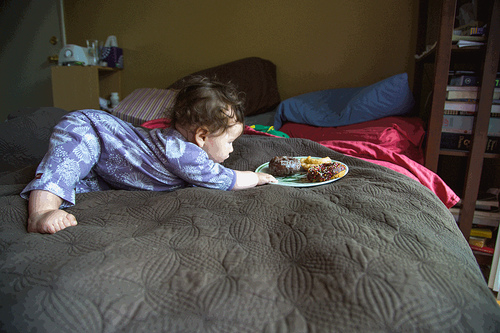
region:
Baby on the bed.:
[23, 78, 275, 240]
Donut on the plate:
[264, 148, 301, 177]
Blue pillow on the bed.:
[255, 65, 417, 135]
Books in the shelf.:
[438, 68, 498, 150]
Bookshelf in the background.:
[415, 4, 495, 276]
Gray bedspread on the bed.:
[6, 133, 494, 326]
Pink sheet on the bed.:
[279, 117, 460, 214]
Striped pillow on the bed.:
[112, 78, 177, 123]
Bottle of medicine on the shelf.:
[107, 88, 120, 105]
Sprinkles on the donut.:
[306, 160, 348, 182]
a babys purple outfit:
[28, 145, 68, 175]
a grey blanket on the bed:
[445, 220, 485, 272]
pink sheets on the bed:
[396, 147, 442, 189]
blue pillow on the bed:
[370, 75, 406, 130]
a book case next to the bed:
[42, 78, 86, 102]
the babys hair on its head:
[215, 80, 250, 120]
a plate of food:
[315, 160, 345, 181]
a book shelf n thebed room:
[435, 81, 485, 131]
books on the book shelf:
[455, 65, 476, 111]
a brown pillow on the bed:
[253, 60, 303, 93]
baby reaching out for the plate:
[86, 78, 403, 236]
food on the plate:
[272, 153, 368, 210]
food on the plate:
[264, 144, 349, 194]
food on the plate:
[243, 126, 360, 209]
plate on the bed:
[253, 140, 348, 214]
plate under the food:
[261, 128, 345, 198]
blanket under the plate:
[277, 188, 347, 248]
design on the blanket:
[219, 179, 340, 266]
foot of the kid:
[28, 192, 84, 247]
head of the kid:
[171, 72, 266, 174]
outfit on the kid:
[27, 110, 213, 225]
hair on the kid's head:
[182, 65, 247, 142]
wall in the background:
[282, 7, 355, 60]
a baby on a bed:
[21, 15, 395, 317]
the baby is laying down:
[22, 47, 413, 325]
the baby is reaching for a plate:
[151, 91, 359, 219]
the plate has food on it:
[262, 141, 353, 242]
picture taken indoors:
[38, 37, 458, 325]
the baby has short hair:
[175, 84, 232, 114]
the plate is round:
[252, 150, 416, 252]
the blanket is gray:
[320, 240, 445, 297]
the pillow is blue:
[302, 94, 394, 111]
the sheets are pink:
[360, 125, 418, 176]